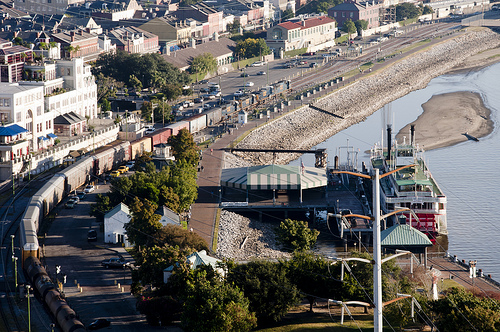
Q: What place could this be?
A: It is a lake.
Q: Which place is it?
A: It is a lake.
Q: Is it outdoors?
A: Yes, it is outdoors.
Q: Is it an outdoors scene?
A: Yes, it is outdoors.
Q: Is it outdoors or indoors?
A: It is outdoors.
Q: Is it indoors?
A: No, it is outdoors.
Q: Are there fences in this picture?
A: No, there are no fences.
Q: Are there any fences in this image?
A: No, there are no fences.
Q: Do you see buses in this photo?
A: No, there are no buses.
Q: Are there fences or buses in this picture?
A: No, there are no buses or fences.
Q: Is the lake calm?
A: Yes, the lake is calm.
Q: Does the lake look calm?
A: Yes, the lake is calm.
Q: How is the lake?
A: The lake is calm.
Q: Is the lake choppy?
A: No, the lake is calm.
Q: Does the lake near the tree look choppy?
A: No, the lake is calm.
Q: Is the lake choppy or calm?
A: The lake is calm.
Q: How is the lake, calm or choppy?
A: The lake is calm.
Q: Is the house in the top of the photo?
A: Yes, the house is in the top of the image.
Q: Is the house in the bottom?
A: No, the house is in the top of the image.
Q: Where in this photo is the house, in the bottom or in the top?
A: The house is in the top of the image.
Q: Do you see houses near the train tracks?
A: Yes, there is a house near the train tracks.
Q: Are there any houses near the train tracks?
A: Yes, there is a house near the train tracks.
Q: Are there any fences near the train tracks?
A: No, there is a house near the train tracks.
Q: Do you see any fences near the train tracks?
A: No, there is a house near the train tracks.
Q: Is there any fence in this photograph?
A: No, there are no fences.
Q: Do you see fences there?
A: No, there are no fences.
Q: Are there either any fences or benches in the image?
A: No, there are no fences or benches.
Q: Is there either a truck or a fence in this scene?
A: No, there are no fences or trucks.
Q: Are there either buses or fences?
A: No, there are no buses or fences.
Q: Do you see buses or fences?
A: No, there are no buses or fences.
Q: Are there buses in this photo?
A: No, there are no buses.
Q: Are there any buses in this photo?
A: No, there are no buses.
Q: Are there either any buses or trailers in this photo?
A: No, there are no buses or trailers.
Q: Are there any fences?
A: No, there are no fences.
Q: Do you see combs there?
A: No, there are no combs.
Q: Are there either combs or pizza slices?
A: No, there are no combs or pizza slices.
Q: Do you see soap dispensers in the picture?
A: No, there are no soap dispensers.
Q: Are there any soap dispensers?
A: No, there are no soap dispensers.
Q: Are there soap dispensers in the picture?
A: No, there are no soap dispensers.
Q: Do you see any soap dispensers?
A: No, there are no soap dispensers.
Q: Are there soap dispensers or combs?
A: No, there are no soap dispensers or combs.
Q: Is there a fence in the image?
A: No, there are no fences.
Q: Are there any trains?
A: Yes, there is a train.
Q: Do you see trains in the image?
A: Yes, there is a train.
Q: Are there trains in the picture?
A: Yes, there is a train.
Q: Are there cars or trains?
A: Yes, there is a train.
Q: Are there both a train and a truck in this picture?
A: No, there is a train but no trucks.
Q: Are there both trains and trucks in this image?
A: No, there is a train but no trucks.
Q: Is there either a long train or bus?
A: Yes, there is a long train.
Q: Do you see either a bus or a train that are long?
A: Yes, the train is long.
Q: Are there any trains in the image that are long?
A: Yes, there is a long train.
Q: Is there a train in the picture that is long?
A: Yes, there is a train that is long.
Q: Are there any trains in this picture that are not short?
A: Yes, there is a long train.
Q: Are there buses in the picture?
A: No, there are no buses.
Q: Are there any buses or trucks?
A: No, there are no buses or trucks.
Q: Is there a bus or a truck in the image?
A: No, there are no buses or trucks.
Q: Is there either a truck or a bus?
A: No, there are no buses or trucks.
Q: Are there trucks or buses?
A: No, there are no buses or trucks.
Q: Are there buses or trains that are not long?
A: No, there is a train but it is long.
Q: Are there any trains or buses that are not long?
A: No, there is a train but it is long.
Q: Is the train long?
A: Yes, the train is long.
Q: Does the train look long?
A: Yes, the train is long.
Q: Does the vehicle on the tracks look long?
A: Yes, the train is long.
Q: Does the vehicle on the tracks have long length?
A: Yes, the train is long.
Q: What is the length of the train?
A: The train is long.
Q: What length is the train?
A: The train is long.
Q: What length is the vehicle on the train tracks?
A: The train is long.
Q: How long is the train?
A: The train is long.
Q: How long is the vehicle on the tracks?
A: The train is long.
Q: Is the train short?
A: No, the train is long.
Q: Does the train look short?
A: No, the train is long.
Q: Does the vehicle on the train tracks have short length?
A: No, the train is long.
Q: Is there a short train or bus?
A: No, there is a train but it is long.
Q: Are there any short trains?
A: No, there is a train but it is long.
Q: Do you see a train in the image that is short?
A: No, there is a train but it is long.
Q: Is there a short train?
A: No, there is a train but it is long.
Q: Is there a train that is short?
A: No, there is a train but it is long.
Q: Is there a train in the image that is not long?
A: No, there is a train but it is long.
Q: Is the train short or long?
A: The train is long.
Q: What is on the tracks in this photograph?
A: The train is on the tracks.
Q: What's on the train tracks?
A: The train is on the tracks.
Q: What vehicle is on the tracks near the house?
A: The vehicle is a train.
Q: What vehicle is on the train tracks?
A: The vehicle is a train.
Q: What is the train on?
A: The train is on the tracks.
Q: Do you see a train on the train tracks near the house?
A: Yes, there is a train on the tracks.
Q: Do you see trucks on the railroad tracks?
A: No, there is a train on the railroad tracks.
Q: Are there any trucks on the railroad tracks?
A: No, there is a train on the railroad tracks.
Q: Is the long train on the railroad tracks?
A: Yes, the train is on the railroad tracks.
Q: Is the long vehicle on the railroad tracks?
A: Yes, the train is on the railroad tracks.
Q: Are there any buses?
A: No, there are no buses.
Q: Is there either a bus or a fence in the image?
A: No, there are no buses or fences.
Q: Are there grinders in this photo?
A: No, there are no grinders.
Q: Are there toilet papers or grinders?
A: No, there are no grinders or toilet papers.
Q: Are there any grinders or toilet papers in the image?
A: No, there are no grinders or toilet papers.